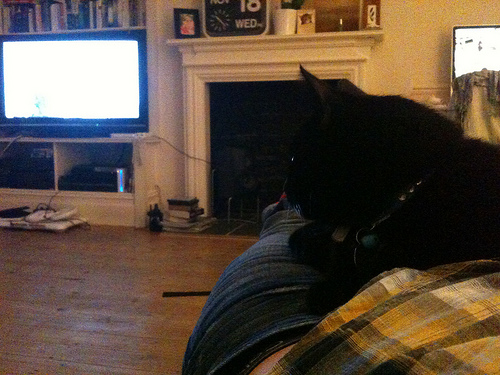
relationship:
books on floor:
[155, 191, 217, 238] [0, 220, 266, 375]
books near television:
[0, 1, 150, 37] [0, 21, 154, 147]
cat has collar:
[273, 59, 499, 322] [338, 138, 460, 265]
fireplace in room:
[165, 27, 390, 228] [3, 0, 499, 374]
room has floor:
[3, 0, 499, 374] [0, 220, 266, 375]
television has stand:
[0, 21, 154, 147] [0, 134, 166, 236]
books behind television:
[0, 1, 150, 37] [0, 21, 154, 147]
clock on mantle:
[200, 0, 272, 40] [164, 27, 389, 73]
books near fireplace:
[155, 191, 217, 238] [165, 27, 390, 228]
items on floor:
[0, 200, 96, 242] [0, 220, 266, 375]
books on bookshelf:
[0, 1, 150, 37] [0, 0, 156, 35]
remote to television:
[0, 202, 35, 218] [0, 21, 154, 147]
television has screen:
[0, 21, 154, 147] [1, 38, 141, 123]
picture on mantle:
[178, 12, 195, 37] [164, 27, 389, 73]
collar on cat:
[338, 138, 460, 265] [273, 59, 499, 322]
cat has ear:
[273, 59, 499, 322] [294, 57, 344, 125]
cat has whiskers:
[273, 59, 499, 322] [282, 197, 312, 238]